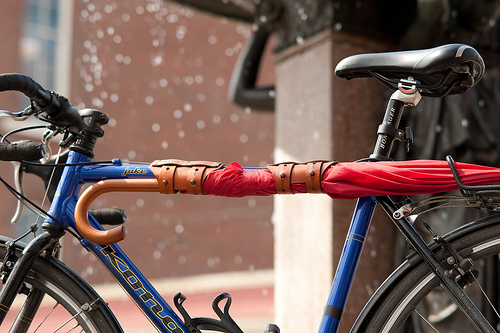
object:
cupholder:
[172, 292, 280, 332]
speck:
[141, 88, 160, 112]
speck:
[169, 102, 185, 123]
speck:
[124, 143, 142, 167]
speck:
[226, 110, 245, 131]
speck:
[147, 49, 172, 75]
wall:
[2, 0, 263, 282]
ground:
[0, 269, 279, 333]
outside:
[0, 0, 500, 332]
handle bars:
[0, 72, 109, 224]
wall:
[265, 21, 424, 330]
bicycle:
[0, 43, 499, 331]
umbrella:
[73, 159, 500, 246]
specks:
[203, 18, 253, 59]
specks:
[127, 195, 165, 217]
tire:
[348, 212, 500, 332]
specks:
[199, 244, 263, 276]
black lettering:
[100, 246, 190, 333]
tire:
[0, 233, 126, 332]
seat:
[332, 43, 484, 96]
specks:
[80, 1, 190, 47]